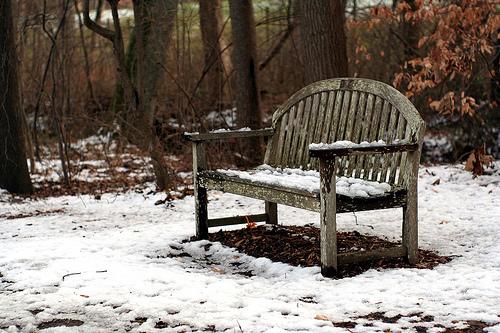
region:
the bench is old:
[49, 67, 235, 293]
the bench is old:
[222, 111, 410, 233]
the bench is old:
[216, 62, 444, 324]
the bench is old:
[186, 59, 368, 253]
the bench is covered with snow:
[176, 47, 362, 267]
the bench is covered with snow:
[220, 61, 458, 326]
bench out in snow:
[127, 58, 465, 308]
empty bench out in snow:
[104, 56, 462, 297]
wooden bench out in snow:
[110, 24, 456, 311]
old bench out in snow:
[148, 48, 461, 301]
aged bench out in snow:
[118, 52, 464, 291]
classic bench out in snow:
[151, 44, 453, 284]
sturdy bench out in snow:
[132, 53, 461, 295]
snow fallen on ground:
[15, 193, 177, 312]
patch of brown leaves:
[388, 1, 487, 85]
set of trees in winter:
[5, 5, 201, 143]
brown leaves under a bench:
[221, 216, 305, 263]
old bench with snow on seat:
[219, 60, 426, 275]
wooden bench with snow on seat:
[227, 97, 400, 254]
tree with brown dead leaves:
[408, 3, 498, 98]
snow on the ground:
[50, 244, 273, 327]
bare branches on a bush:
[52, 68, 162, 179]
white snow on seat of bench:
[233, 154, 317, 195]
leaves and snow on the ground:
[35, 152, 138, 207]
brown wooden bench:
[222, 49, 428, 278]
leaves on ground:
[67, 159, 149, 193]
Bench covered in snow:
[191, 75, 432, 270]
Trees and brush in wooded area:
[0, 0, 491, 70]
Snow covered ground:
[0, 198, 498, 326]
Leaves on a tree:
[351, 0, 496, 135]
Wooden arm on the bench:
[190, 122, 280, 233]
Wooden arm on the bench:
[310, 147, 425, 272]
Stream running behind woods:
[51, 0, 451, 30]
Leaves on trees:
[17, 26, 265, 96]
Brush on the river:
[5, 17, 281, 102]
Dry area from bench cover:
[226, 221, 440, 274]